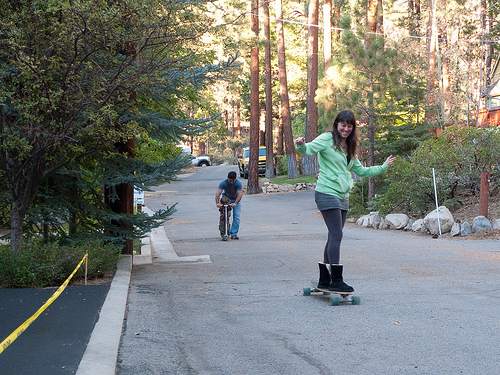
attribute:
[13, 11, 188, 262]
tree — big, growing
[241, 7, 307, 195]
trunks — narrow, long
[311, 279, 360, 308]
skateboard — black, long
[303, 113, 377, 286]
woman — skating, smiling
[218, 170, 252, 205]
man — hunched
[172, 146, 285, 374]
street — quiet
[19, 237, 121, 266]
bush — green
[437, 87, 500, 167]
house — brown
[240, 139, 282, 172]
truck — red, parked, yellow, white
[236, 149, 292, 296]
road — grey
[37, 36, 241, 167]
trees — green, growing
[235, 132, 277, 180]
car — parked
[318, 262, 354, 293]
shoes — black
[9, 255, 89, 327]
rope — yellow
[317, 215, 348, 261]
pants — grey, gray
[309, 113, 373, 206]
girl — cute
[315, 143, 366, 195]
jacket — green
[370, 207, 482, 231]
rocks — huge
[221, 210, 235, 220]
shirt — blue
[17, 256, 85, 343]
tape — yellow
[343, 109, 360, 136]
hair — dark, long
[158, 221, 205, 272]
marker — white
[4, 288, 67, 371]
driveway — paved, fresh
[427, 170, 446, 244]
post — white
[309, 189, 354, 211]
skirt — gray